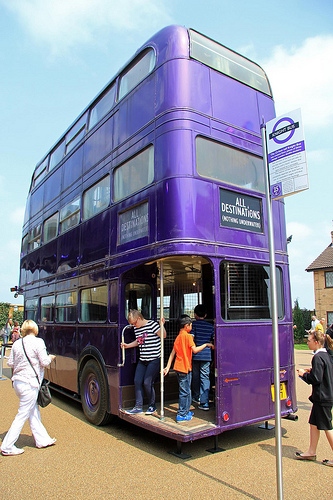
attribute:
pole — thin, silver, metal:
[259, 123, 283, 498]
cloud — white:
[6, 0, 175, 62]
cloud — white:
[237, 34, 332, 130]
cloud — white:
[304, 146, 332, 161]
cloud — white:
[287, 218, 332, 306]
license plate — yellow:
[270, 380, 288, 403]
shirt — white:
[11, 340, 49, 381]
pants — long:
[177, 365, 197, 430]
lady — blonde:
[0, 317, 55, 454]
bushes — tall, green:
[291, 295, 316, 342]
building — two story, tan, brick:
[16, 11, 300, 445]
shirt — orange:
[172, 329, 199, 375]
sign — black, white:
[219, 187, 263, 232]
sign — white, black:
[117, 201, 147, 245]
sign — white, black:
[265, 107, 308, 200]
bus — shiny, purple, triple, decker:
[0, 27, 320, 451]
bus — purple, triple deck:
[13, 20, 302, 461]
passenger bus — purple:
[8, 21, 305, 458]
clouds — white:
[273, 32, 331, 102]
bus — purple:
[23, 68, 312, 365]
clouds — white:
[0, 0, 332, 137]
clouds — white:
[262, 33, 322, 126]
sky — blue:
[3, 1, 322, 306]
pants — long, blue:
[131, 355, 163, 408]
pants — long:
[189, 357, 213, 407]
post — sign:
[259, 124, 284, 498]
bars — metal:
[167, 432, 227, 459]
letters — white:
[222, 198, 256, 234]